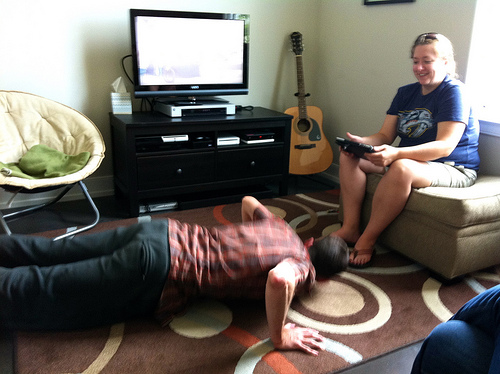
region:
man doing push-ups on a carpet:
[8, 192, 357, 357]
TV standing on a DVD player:
[134, 5, 263, 114]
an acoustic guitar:
[282, 33, 335, 177]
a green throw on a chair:
[5, 140, 112, 183]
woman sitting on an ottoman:
[367, 39, 499, 259]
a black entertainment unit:
[113, 112, 287, 199]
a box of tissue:
[108, 74, 137, 117]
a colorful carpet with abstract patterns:
[323, 287, 418, 364]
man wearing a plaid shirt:
[176, 211, 309, 276]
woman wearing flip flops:
[347, 241, 384, 274]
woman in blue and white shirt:
[335, 25, 464, 160]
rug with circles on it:
[153, 285, 428, 372]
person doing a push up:
[1, 215, 342, 322]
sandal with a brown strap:
[333, 221, 393, 299]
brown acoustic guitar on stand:
[276, 65, 333, 194]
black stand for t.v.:
[106, 101, 297, 225]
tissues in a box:
[85, 69, 136, 131]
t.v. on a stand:
[77, 65, 264, 166]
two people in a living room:
[118, 65, 486, 337]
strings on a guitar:
[290, 61, 307, 138]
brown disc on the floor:
[316, 285, 388, 330]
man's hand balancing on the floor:
[250, 296, 343, 348]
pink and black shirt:
[175, 215, 301, 280]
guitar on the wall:
[278, 31, 352, 193]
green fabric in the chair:
[18, 135, 82, 181]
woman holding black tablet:
[324, 126, 394, 178]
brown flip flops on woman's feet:
[328, 222, 398, 272]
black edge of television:
[103, 0, 253, 107]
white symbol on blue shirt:
[393, 94, 432, 141]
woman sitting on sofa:
[321, 22, 495, 247]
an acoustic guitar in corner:
[280, 33, 330, 187]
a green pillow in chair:
[6, 142, 87, 181]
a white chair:
[0, 104, 110, 242]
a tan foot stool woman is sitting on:
[334, 117, 499, 292]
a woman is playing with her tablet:
[333, 125, 378, 168]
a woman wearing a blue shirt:
[375, 37, 479, 148]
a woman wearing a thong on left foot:
[351, 240, 387, 279]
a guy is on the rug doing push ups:
[0, 190, 350, 345]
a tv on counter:
[128, 6, 257, 113]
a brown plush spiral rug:
[5, 250, 449, 361]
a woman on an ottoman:
[318, 18, 483, 268]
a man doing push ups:
[15, 180, 337, 355]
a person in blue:
[412, 280, 494, 365]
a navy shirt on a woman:
[385, 65, 480, 161]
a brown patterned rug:
[0, 175, 495, 360]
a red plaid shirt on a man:
[156, 205, 307, 305]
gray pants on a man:
[0, 205, 171, 315]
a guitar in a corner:
[275, 20, 340, 180]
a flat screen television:
[115, 0, 260, 100]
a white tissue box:
[96, 70, 138, 125]